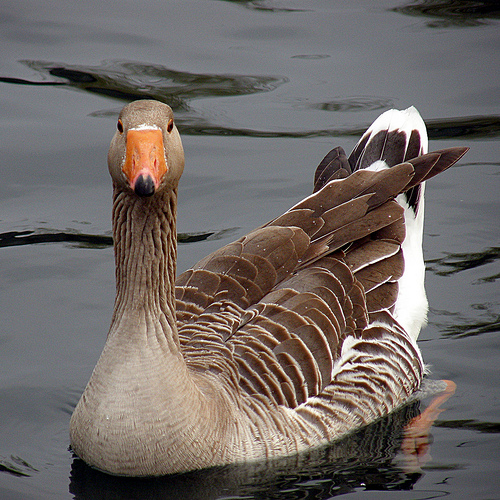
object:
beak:
[121, 126, 170, 198]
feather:
[180, 176, 391, 369]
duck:
[66, 99, 470, 478]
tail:
[313, 103, 471, 238]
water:
[2, 4, 497, 240]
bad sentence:
[303, 108, 341, 138]